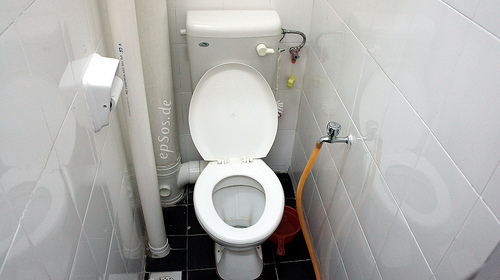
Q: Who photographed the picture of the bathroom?
A: Business owner.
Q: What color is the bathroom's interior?
A: White.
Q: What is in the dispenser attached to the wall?
A: Tissue.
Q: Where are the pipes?
A: Beside the wall.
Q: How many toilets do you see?
A: 1.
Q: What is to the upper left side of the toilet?
A: Toilet paper.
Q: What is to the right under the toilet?
A: A red bucket.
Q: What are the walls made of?
A: Tiles.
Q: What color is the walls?
A: White.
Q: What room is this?
A: The bathroom.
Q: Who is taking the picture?
A: A photographer.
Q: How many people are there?
A: None.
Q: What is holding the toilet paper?
A: Holder.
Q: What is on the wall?
A: Reflection.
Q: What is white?
A: Wall.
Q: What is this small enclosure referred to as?
A: A stall.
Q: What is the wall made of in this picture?
A: White tiles.